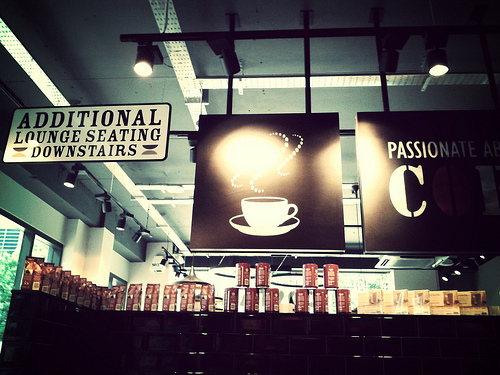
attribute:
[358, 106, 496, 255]
sign — black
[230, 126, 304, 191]
dots — twisted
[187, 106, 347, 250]
sign — square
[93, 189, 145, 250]
lights — angled differently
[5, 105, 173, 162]
sign — informational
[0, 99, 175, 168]
sign — informational, white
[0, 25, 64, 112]
beams — metal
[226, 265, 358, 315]
cans — red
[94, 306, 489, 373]
drawers — black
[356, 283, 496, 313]
boxes — beige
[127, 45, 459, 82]
two lights — on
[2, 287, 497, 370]
counter — dark brown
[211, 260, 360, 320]
boxes — red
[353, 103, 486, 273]
sign — one